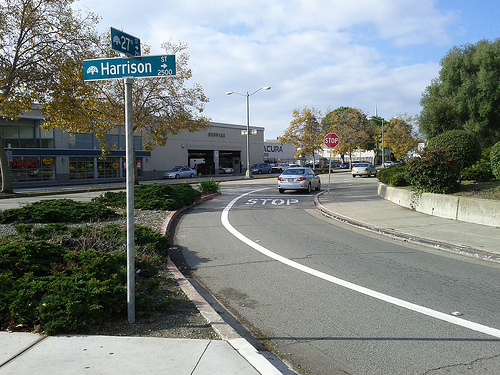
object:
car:
[277, 166, 322, 194]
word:
[12, 159, 40, 167]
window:
[12, 155, 57, 182]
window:
[69, 156, 95, 181]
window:
[97, 157, 121, 179]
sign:
[323, 132, 340, 148]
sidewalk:
[0, 331, 270, 375]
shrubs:
[0, 182, 204, 337]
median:
[1, 181, 285, 373]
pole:
[328, 148, 333, 194]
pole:
[123, 77, 136, 323]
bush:
[402, 145, 461, 194]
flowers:
[418, 149, 430, 156]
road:
[169, 184, 500, 375]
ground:
[375, 213, 432, 220]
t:
[260, 198, 272, 204]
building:
[0, 101, 143, 189]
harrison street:
[101, 61, 152, 76]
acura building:
[264, 142, 296, 163]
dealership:
[264, 145, 284, 157]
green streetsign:
[110, 26, 142, 57]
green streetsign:
[82, 54, 176, 82]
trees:
[276, 103, 426, 171]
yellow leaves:
[302, 123, 367, 146]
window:
[0, 117, 56, 150]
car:
[162, 165, 197, 179]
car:
[209, 165, 234, 174]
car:
[250, 163, 272, 175]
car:
[272, 163, 290, 173]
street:
[0, 162, 500, 375]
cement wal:
[377, 182, 500, 226]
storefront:
[1, 109, 149, 188]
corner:
[0, 176, 265, 375]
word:
[264, 145, 284, 152]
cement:
[0, 331, 254, 375]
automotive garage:
[141, 114, 265, 177]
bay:
[219, 149, 243, 175]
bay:
[187, 148, 215, 175]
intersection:
[195, 176, 376, 194]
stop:
[245, 198, 299, 205]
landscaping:
[376, 36, 500, 196]